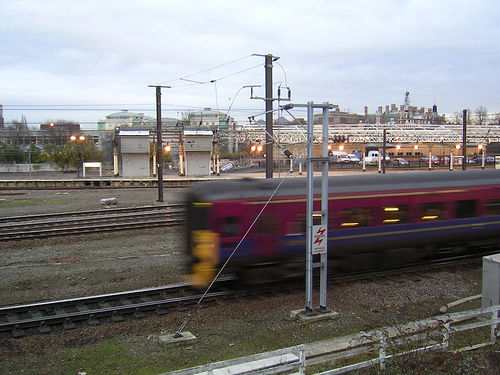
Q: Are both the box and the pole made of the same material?
A: Yes, both the box and the pole are made of metal.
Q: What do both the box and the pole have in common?
A: The material, both the box and the pole are metallic.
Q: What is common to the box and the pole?
A: The material, both the box and the pole are metallic.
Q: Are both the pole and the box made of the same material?
A: Yes, both the pole and the box are made of metal.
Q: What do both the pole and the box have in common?
A: The material, both the pole and the box are metallic.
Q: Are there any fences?
A: Yes, there is a fence.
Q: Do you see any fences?
A: Yes, there is a fence.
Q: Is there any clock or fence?
A: Yes, there is a fence.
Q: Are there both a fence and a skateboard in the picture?
A: No, there is a fence but no skateboards.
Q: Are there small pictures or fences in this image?
A: Yes, there is a small fence.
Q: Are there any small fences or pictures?
A: Yes, there is a small fence.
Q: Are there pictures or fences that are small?
A: Yes, the fence is small.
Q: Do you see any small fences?
A: Yes, there is a small fence.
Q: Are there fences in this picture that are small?
A: Yes, there is a fence that is small.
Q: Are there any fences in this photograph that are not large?
A: Yes, there is a small fence.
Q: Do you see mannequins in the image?
A: No, there are no mannequins.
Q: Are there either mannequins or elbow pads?
A: No, there are no mannequins or elbow pads.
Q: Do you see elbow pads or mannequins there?
A: No, there are no mannequins or elbow pads.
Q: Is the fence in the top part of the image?
A: No, the fence is in the bottom of the image.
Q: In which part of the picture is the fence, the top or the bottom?
A: The fence is in the bottom of the image.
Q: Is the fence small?
A: Yes, the fence is small.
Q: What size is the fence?
A: The fence is small.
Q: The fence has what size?
A: The fence is small.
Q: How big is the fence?
A: The fence is small.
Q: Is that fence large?
A: No, the fence is small.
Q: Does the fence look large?
A: No, the fence is small.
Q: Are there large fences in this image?
A: No, there is a fence but it is small.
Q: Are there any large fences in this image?
A: No, there is a fence but it is small.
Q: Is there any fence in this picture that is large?
A: No, there is a fence but it is small.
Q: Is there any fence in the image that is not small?
A: No, there is a fence but it is small.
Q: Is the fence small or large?
A: The fence is small.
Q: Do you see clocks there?
A: No, there are no clocks.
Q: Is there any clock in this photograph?
A: No, there are no clocks.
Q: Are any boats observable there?
A: No, there are no boats.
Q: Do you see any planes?
A: No, there are no planes.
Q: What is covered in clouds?
A: The sky is covered in clouds.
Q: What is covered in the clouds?
A: The sky is covered in clouds.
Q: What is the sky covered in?
A: The sky is covered in clouds.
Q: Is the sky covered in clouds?
A: Yes, the sky is covered in clouds.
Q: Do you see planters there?
A: No, there are no planters.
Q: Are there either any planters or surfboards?
A: No, there are no planters or surfboards.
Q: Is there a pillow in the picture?
A: No, there are no pillows.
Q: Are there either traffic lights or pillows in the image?
A: No, there are no pillows or traffic lights.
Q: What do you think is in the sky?
A: The clouds are in the sky.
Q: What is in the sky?
A: The clouds are in the sky.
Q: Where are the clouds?
A: The clouds are in the sky.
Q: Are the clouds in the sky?
A: Yes, the clouds are in the sky.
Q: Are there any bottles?
A: No, there are no bottles.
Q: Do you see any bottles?
A: No, there are no bottles.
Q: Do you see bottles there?
A: No, there are no bottles.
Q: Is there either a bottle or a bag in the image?
A: No, there are no bottles or bags.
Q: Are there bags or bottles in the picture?
A: No, there are no bottles or bags.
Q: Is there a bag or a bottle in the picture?
A: No, there are no bottles or bags.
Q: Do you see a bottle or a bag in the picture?
A: No, there are no bottles or bags.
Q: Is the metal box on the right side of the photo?
A: Yes, the box is on the right of the image.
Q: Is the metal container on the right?
A: Yes, the box is on the right of the image.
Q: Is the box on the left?
A: No, the box is on the right of the image.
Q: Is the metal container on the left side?
A: No, the box is on the right of the image.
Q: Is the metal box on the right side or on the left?
A: The box is on the right of the image.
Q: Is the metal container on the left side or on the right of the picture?
A: The box is on the right of the image.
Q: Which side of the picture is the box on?
A: The box is on the right of the image.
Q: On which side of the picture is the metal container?
A: The box is on the right of the image.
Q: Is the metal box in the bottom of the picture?
A: Yes, the box is in the bottom of the image.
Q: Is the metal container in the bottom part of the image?
A: Yes, the box is in the bottom of the image.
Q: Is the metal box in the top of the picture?
A: No, the box is in the bottom of the image.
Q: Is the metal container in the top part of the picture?
A: No, the box is in the bottom of the image.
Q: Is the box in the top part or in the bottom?
A: The box is in the bottom of the image.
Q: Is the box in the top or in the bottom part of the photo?
A: The box is in the bottom of the image.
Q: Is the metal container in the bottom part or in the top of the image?
A: The box is in the bottom of the image.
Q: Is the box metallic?
A: Yes, the box is metallic.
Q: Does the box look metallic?
A: Yes, the box is metallic.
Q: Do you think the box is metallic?
A: Yes, the box is metallic.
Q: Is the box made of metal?
A: Yes, the box is made of metal.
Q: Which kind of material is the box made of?
A: The box is made of metal.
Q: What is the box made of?
A: The box is made of metal.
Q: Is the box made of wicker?
A: No, the box is made of metal.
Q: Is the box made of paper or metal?
A: The box is made of metal.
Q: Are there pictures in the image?
A: No, there are no pictures.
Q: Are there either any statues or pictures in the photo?
A: No, there are no pictures or statues.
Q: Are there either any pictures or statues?
A: No, there are no pictures or statues.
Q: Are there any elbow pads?
A: No, there are no elbow pads.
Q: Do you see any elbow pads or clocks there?
A: No, there are no elbow pads or clocks.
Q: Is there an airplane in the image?
A: No, there are no airplanes.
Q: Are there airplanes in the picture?
A: No, there are no airplanes.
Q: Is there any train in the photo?
A: Yes, there is a train.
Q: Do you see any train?
A: Yes, there is a train.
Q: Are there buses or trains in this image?
A: Yes, there is a train.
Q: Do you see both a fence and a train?
A: Yes, there are both a train and a fence.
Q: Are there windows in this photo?
A: Yes, there are windows.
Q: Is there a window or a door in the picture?
A: Yes, there are windows.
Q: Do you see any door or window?
A: Yes, there are windows.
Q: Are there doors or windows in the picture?
A: Yes, there are windows.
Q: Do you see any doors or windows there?
A: Yes, there are windows.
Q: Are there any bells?
A: No, there are no bells.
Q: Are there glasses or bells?
A: No, there are no bells or glasses.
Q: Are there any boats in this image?
A: No, there are no boats.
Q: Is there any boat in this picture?
A: No, there are no boats.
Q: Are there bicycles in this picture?
A: No, there are no bicycles.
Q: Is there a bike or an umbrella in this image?
A: No, there are no bikes or umbrellas.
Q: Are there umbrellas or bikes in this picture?
A: No, there are no bikes or umbrellas.